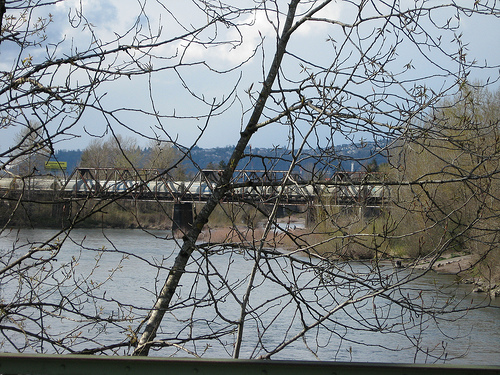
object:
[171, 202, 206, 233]
bridge support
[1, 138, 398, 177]
hill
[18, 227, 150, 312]
calm water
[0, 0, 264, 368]
tree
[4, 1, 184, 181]
no leaves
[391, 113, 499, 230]
brown leaves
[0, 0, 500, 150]
clear sky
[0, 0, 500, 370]
river scene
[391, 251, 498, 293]
beach area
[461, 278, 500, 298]
rocks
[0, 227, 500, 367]
river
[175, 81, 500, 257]
bush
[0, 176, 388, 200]
train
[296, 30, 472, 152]
leaves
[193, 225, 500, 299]
river bank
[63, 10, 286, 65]
clouds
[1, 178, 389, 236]
bridge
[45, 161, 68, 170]
billboard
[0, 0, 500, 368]
branch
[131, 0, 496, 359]
tree